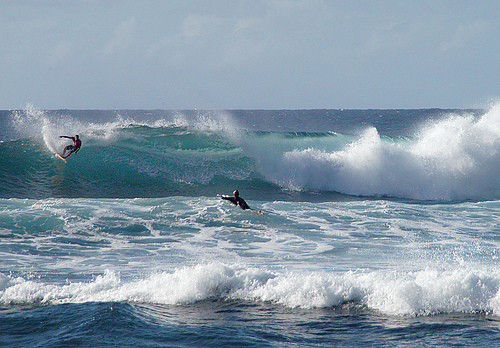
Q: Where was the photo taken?
A: The ocean.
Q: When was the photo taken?
A: Daytime.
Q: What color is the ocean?
A: Blue.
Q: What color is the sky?
A: Gray.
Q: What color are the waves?
A: White.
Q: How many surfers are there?
A: Two.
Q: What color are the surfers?
A: Black.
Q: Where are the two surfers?
A: In the ocean.